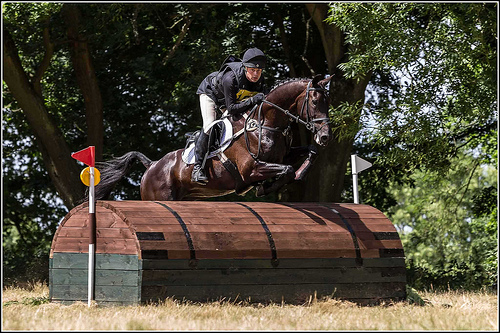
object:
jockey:
[189, 47, 269, 186]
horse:
[77, 72, 334, 206]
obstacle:
[45, 196, 412, 308]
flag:
[70, 143, 97, 166]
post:
[88, 168, 99, 309]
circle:
[79, 165, 101, 187]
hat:
[242, 46, 268, 71]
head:
[243, 57, 265, 83]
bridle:
[243, 96, 311, 162]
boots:
[192, 129, 213, 188]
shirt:
[195, 62, 269, 118]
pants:
[198, 93, 217, 137]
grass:
[2, 275, 499, 331]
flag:
[351, 152, 373, 175]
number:
[236, 89, 261, 104]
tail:
[73, 150, 154, 205]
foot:
[191, 164, 211, 185]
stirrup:
[192, 164, 211, 185]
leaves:
[1, 2, 497, 290]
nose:
[310, 121, 334, 149]